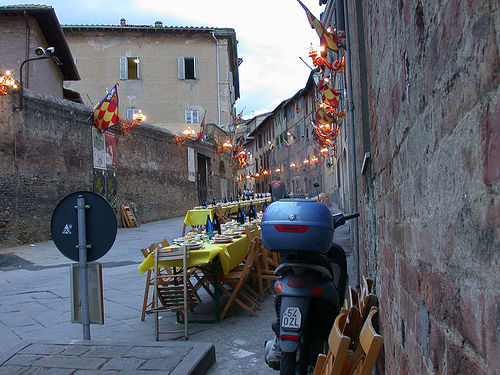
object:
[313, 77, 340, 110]
flag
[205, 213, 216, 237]
bottles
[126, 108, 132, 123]
window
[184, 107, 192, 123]
window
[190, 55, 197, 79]
shutter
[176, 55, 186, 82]
shutter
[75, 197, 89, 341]
post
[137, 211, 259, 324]
tables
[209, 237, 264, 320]
chairs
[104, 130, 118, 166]
poster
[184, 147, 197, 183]
poster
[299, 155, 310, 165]
lights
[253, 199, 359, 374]
motorcycle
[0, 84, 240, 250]
concrete wall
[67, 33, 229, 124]
concrete wall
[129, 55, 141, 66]
light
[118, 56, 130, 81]
window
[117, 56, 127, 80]
shutters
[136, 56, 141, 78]
shutters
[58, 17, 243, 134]
building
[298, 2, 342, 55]
flag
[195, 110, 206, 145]
flag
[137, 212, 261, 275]
table cloth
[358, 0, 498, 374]
wall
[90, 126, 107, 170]
poster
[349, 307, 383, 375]
chairs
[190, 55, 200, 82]
window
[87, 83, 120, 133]
flag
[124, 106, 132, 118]
shutters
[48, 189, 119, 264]
sign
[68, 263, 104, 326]
sign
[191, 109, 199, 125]
window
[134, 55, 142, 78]
window